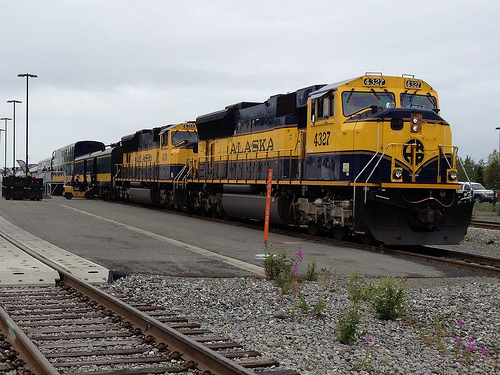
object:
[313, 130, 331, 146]
4327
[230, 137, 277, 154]
alaska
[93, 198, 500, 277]
train track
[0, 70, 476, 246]
train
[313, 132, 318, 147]
4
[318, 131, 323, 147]
3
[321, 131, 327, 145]
2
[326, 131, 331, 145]
7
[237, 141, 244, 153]
l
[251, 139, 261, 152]
s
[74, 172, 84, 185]
man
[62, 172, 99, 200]
forklift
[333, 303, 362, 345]
weed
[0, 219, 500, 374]
gravel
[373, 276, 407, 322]
weed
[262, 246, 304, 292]
weed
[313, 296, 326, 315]
weed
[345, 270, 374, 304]
weed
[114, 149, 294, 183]
railing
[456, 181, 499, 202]
parking lot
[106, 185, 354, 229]
gears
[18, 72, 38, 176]
light pole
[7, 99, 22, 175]
light pole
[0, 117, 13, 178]
light pole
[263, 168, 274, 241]
warning sign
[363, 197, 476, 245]
bumper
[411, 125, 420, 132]
center headlight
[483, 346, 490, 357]
flower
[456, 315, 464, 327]
flower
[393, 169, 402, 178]
headlight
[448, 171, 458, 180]
headlight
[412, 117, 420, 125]
center headlight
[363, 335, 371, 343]
flower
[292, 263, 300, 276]
flower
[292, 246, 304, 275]
flower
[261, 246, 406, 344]
weeds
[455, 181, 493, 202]
car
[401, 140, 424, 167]
symbol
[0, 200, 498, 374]
tracks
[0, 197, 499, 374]
ground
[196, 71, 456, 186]
train car